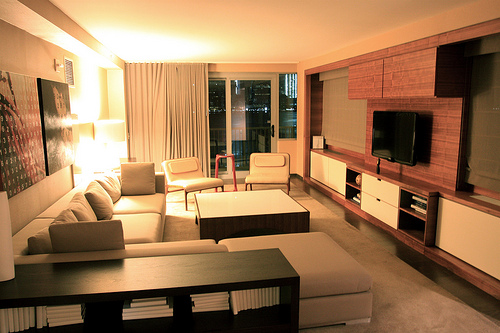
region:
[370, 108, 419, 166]
Television on a wall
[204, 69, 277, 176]
Sliding glass door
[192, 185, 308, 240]
Coffee table with a white top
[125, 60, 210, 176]
White curtain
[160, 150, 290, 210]
Pair of white chairs in front of a glass door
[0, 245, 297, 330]
Black bookshelf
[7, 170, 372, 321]
White couch with pillows on it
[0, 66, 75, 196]
Pair of paintings on the wall above a couch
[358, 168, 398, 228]
Pair of white drawers below a television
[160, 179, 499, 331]
Rug on the floor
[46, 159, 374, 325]
Large white sectional couch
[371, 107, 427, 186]
tv mounted on wall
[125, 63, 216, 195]
Long curtain in front of window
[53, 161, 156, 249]
White pillows on couch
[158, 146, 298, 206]
Two white chairs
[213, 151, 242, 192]
Red table between chairs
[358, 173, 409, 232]
Two white drawers under tv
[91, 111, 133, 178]
Lamp sitting on table is on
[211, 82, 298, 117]
Lights of the city out the window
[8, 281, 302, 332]
Many books on black shelf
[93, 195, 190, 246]
the sofa is white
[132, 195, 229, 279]
the sofa is white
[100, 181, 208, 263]
the sofa is white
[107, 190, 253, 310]
the sofa is white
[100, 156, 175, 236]
the sofa is white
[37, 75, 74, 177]
large modern art painting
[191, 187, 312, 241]
square shaped coffee table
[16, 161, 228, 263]
couch with throw pillows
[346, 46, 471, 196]
television mounted on the wall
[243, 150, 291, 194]
chair with built in back rest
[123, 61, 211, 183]
floor to ceiling curtains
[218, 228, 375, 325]
square ottoman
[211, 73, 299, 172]
lights visible through window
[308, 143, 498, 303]
wall mounted storage area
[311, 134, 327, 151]
framed picture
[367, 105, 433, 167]
Flat screen tv attached to wall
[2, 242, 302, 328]
Dark brown cabnet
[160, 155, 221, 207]
Beige chair with pillows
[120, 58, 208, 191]
Beige curtains hanging in front of window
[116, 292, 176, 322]
Stack of books in cabinet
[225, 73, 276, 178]
Door to enter room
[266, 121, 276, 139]
Black handle on door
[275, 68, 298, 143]
Oblong window next to door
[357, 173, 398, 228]
Beige cabinet drawers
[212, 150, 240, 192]
Tall glass and wood table